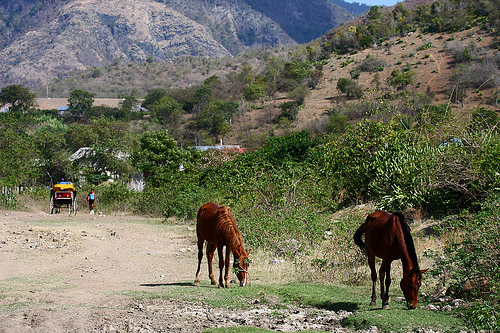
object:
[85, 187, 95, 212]
woman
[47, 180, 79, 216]
carriage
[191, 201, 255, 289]
horse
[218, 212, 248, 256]
mane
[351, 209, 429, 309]
horse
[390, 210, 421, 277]
mane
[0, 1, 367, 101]
mountains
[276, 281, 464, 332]
grass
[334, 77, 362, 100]
shrub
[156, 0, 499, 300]
hill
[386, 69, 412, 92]
shrub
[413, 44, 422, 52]
shrub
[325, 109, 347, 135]
shrub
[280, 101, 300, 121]
shrub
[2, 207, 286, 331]
dirt road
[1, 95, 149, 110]
roof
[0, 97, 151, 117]
building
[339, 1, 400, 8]
sky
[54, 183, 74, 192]
load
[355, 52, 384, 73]
shrub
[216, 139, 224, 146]
stack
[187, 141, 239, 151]
roof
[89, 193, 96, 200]
shirt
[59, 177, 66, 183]
man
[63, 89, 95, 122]
trees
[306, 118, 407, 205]
vegetation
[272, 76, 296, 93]
shrub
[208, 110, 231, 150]
shrub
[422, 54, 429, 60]
shrub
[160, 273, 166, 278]
rock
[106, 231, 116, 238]
rock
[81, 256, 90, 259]
rock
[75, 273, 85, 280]
rock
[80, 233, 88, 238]
rock